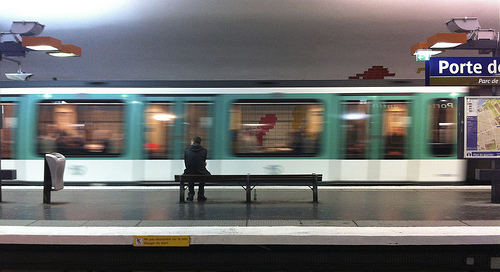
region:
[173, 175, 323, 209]
long black bench on platform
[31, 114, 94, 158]
person sitting in the car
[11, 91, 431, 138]
train is green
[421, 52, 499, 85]
sign is in blue and white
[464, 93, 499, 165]
map is below the sign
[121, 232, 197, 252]
yellow sign on the side of platform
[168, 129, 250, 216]
man sitting on the bench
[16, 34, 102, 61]
two lights in the ceiling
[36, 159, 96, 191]
silver item in the middle of floor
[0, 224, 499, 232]
white marking on the side of platform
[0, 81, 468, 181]
a moving green and white train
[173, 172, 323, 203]
a train station bench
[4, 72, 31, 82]
a white security camera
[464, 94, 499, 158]
a large framed map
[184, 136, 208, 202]
a man sitting on bench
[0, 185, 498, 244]
a passenger boarding platform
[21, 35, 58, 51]
an overhead platform light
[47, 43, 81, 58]
an overhead platform light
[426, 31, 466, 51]
an overhead platform light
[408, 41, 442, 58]
an overhead platform light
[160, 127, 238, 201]
person is sitting on a bench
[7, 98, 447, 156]
train going by fast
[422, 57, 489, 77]
sign with blue background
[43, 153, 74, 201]
silver item on pavement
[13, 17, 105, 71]
lights on ceiling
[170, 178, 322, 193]
black bench by trains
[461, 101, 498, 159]
picture of a map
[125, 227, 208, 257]
yellow sign on side of platform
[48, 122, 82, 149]
person sitting in the car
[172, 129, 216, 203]
the man on the bench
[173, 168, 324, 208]
the bench under the man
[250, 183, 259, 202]
the drink on the train platform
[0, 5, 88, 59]
the lights on the train platform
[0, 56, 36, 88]
the camera hanging on the platform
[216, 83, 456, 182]
the blur of the train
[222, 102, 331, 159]
the window on the train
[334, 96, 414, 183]
the door of the train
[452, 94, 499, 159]
the city sign on the train paltform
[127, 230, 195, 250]
the yellow sign on the platform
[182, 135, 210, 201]
the man sitting on the bench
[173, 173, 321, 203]
the bench the man is sitting on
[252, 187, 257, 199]
the green bottle near the bench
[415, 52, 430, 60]
the small green sign with an arrow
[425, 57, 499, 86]
the portion of a blue sign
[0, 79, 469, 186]
the moving train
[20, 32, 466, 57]
the lights above the train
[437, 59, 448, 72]
the letter "P" on the sign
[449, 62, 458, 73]
the letter "o" on the train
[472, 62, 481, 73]
the letter "e" on the sign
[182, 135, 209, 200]
sitting man all in black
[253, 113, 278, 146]
red pattern on wall on the other side of train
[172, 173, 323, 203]
black bench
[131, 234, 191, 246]
yellow sign on the side of the platform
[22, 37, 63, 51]
square orange light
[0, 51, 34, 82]
hanging security camera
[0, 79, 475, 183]
moving green and white train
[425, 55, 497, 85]
blue location sign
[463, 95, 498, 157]
large map hanging on a pole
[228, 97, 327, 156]
large train window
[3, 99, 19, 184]
window on a train